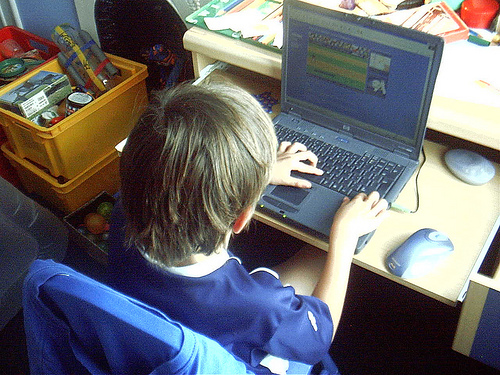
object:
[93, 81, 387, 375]
boy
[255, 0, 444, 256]
laptop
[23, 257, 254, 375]
shirt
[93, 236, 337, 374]
shirt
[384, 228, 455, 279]
mouse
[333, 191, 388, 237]
hands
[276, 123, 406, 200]
keyboard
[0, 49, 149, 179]
bin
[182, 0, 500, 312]
desk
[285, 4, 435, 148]
screen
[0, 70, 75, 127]
box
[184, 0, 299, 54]
book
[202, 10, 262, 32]
papers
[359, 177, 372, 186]
keys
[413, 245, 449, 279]
light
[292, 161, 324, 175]
fingers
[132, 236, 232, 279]
collar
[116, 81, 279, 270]
hair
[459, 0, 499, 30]
cotaier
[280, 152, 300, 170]
part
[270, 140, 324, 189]
hand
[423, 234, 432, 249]
part